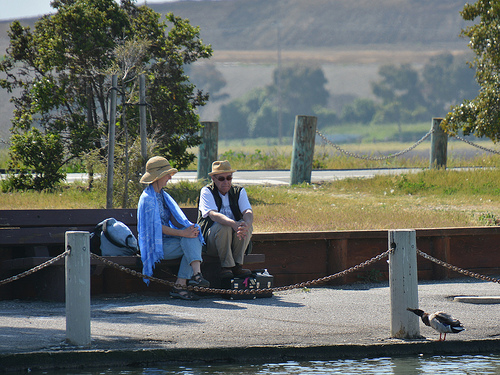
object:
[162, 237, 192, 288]
legs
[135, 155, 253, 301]
couple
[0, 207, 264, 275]
bench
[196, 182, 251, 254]
vest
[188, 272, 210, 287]
shoes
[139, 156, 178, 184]
hat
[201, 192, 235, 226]
arm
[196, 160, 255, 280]
man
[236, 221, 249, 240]
hands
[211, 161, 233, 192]
head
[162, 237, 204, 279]
brown pants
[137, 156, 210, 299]
woman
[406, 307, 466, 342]
bird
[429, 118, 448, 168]
pole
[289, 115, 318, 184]
pole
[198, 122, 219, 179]
pole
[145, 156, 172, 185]
head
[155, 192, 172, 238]
shirt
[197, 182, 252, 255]
shirt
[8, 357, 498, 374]
water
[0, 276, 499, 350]
path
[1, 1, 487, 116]
mountain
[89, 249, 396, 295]
metal fence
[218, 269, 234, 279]
feet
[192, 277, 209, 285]
foot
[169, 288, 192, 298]
foot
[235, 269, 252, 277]
foot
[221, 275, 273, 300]
case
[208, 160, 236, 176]
hat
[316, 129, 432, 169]
fence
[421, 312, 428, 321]
neck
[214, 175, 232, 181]
glasses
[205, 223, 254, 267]
pants